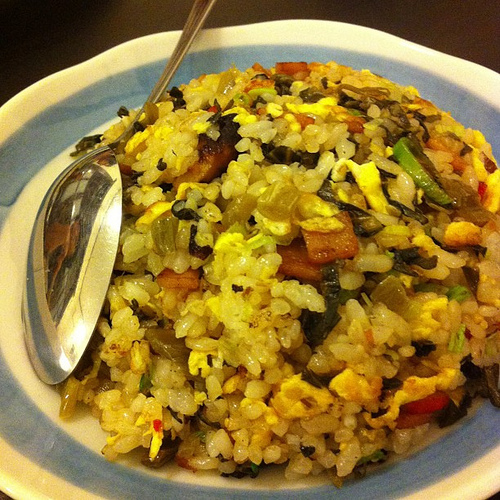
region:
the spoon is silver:
[20, 26, 233, 381]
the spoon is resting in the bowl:
[15, 2, 235, 378]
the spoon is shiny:
[20, 3, 227, 380]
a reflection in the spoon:
[34, 195, 100, 298]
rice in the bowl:
[150, 230, 365, 474]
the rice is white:
[153, 237, 386, 471]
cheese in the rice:
[257, 364, 353, 426]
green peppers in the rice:
[376, 134, 452, 221]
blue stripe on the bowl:
[3, 103, 498, 498]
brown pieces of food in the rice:
[295, 183, 360, 268]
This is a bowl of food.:
[43, 79, 485, 495]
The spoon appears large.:
[25, 10, 227, 406]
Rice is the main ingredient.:
[184, 309, 427, 482]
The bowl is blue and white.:
[6, 22, 489, 493]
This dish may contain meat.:
[158, 102, 280, 204]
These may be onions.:
[160, 215, 367, 302]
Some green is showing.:
[381, 132, 476, 235]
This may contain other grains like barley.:
[171, 160, 486, 479]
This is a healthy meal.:
[171, 125, 484, 457]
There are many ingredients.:
[171, 144, 477, 476]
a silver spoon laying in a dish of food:
[26, 9, 209, 388]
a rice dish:
[64, 72, 467, 464]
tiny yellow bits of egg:
[271, 363, 323, 430]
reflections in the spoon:
[50, 188, 92, 306]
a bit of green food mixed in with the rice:
[394, 133, 452, 207]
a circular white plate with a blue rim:
[1, 18, 497, 495]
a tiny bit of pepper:
[258, 176, 295, 220]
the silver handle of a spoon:
[127, 0, 227, 142]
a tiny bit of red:
[401, 391, 454, 423]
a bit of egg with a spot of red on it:
[146, 402, 165, 462]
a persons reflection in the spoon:
[45, 184, 97, 300]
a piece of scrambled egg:
[261, 363, 351, 433]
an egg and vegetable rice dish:
[136, 210, 458, 445]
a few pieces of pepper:
[266, 209, 360, 298]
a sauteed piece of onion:
[368, 268, 429, 330]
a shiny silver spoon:
[18, 0, 261, 402]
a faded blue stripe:
[43, 427, 453, 498]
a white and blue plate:
[1, 7, 489, 491]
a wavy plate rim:
[16, 18, 493, 110]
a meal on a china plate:
[18, 75, 488, 485]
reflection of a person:
[45, 219, 86, 299]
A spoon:
[30, 107, 107, 414]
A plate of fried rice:
[133, 92, 480, 487]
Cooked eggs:
[213, 379, 437, 419]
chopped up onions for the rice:
[206, 165, 303, 223]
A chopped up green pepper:
[383, 118, 453, 193]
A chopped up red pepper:
[301, 206, 353, 268]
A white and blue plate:
[11, 29, 428, 486]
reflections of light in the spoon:
[53, 199, 120, 366]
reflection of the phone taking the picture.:
[43, 192, 77, 257]